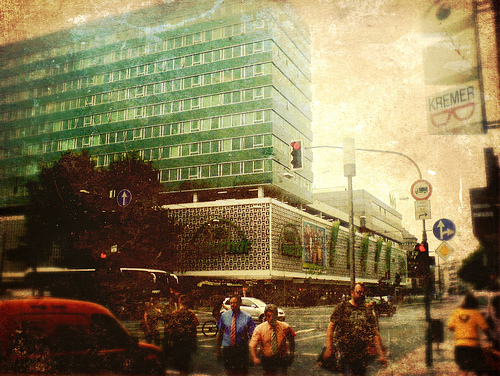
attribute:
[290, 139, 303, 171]
traffic light — red, glowing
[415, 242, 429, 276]
traffic light — red, glowing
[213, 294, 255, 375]
person — walking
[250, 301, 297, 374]
person — walking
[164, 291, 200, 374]
person — walking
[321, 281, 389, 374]
person — walking, heavy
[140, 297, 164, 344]
person — walking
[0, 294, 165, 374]
minivan — red, stopped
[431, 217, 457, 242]
sign — round, blue, circular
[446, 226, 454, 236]
arrow — white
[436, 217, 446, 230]
arrow — white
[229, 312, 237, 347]
tie — orange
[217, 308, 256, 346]
shirt — blue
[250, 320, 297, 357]
shirt — orange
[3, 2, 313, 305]
building — rectangular, green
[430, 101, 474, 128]
glasses — red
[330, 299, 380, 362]
top — camo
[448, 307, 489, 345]
shirt — yellow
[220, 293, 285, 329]
car — white, travelling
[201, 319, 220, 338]
tire — black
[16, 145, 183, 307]
tree — tall